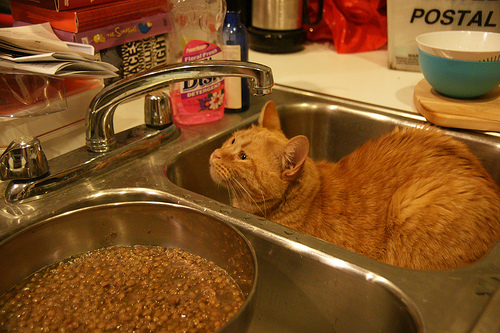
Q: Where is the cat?
A: In the sink.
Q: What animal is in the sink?
A: A cat?.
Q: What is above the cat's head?
A: A faucet.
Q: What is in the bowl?
A: Beans.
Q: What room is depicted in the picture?
A: The kitchen.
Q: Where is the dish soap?
A: Next to the faucet.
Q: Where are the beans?
A: In a bowl.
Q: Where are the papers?
A: Behind the sink.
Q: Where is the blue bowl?
A: Next to the sink.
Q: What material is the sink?
A: Stainless steel.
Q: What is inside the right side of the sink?
A: A cat.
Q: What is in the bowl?
A: Beans.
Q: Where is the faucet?
A: Above the cats head.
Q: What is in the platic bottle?
A: Dish soap.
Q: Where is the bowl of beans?
A: Left sink.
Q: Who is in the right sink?
A: Cat.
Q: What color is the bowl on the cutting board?
A: Blue.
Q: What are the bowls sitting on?
A: Cutting board.